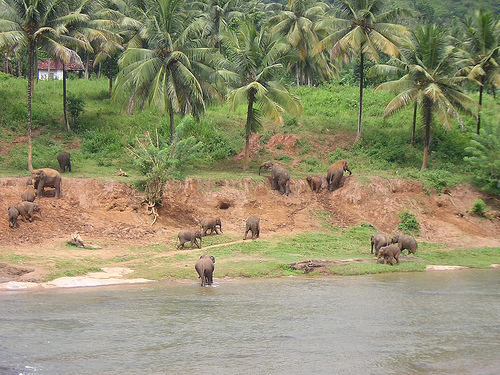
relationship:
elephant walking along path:
[175, 230, 205, 250] [29, 237, 272, 276]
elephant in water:
[193, 252, 218, 286] [0, 267, 499, 374]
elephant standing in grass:
[392, 230, 417, 260] [269, 220, 499, 270]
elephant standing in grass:
[372, 239, 402, 265] [269, 220, 499, 270]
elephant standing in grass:
[367, 229, 393, 251] [269, 220, 499, 270]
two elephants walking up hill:
[258, 158, 352, 195] [1, 39, 484, 273]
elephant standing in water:
[194, 254, 215, 287] [0, 267, 499, 374]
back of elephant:
[199, 254, 209, 269] [192, 249, 221, 290]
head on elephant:
[216, 217, 221, 232] [391, 232, 416, 256]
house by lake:
[33, 58, 85, 80] [0, 265, 497, 374]